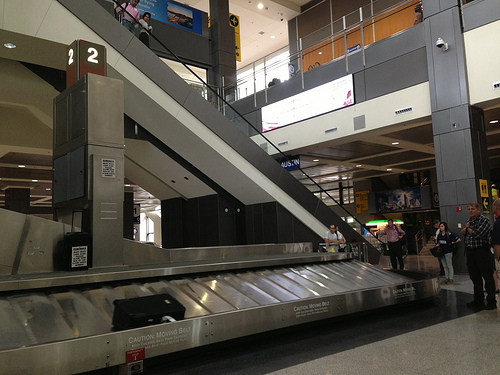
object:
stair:
[72, 0, 387, 267]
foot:
[480, 300, 495, 311]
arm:
[466, 224, 491, 234]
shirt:
[457, 212, 496, 249]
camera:
[434, 37, 447, 49]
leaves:
[346, 86, 354, 98]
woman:
[437, 221, 456, 286]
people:
[324, 222, 349, 252]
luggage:
[112, 288, 186, 331]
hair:
[437, 220, 452, 231]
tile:
[332, 332, 492, 372]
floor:
[142, 272, 500, 373]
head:
[437, 222, 450, 232]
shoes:
[477, 301, 499, 313]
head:
[465, 200, 483, 219]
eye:
[465, 207, 470, 212]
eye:
[472, 205, 477, 210]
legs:
[483, 261, 498, 302]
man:
[459, 201, 496, 310]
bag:
[429, 240, 450, 259]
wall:
[422, 5, 471, 114]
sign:
[260, 71, 355, 136]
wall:
[220, 21, 438, 159]